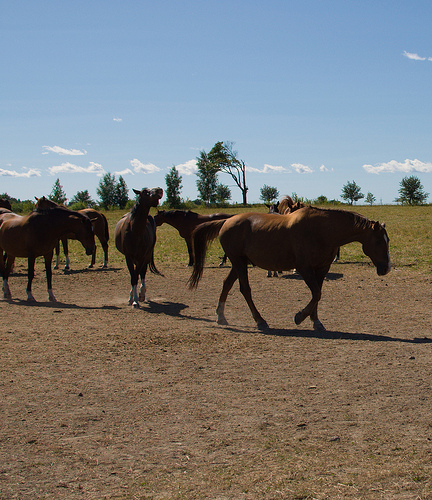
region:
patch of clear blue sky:
[32, 20, 382, 106]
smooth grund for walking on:
[54, 385, 431, 489]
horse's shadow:
[316, 331, 419, 347]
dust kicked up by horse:
[103, 290, 128, 314]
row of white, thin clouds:
[247, 160, 425, 174]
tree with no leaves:
[203, 140, 246, 201]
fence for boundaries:
[371, 198, 393, 209]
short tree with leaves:
[399, 176, 426, 207]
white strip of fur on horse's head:
[379, 231, 392, 248]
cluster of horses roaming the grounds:
[0, 195, 395, 330]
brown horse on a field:
[181, 204, 390, 334]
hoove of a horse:
[310, 317, 322, 328]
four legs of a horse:
[211, 253, 325, 332]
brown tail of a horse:
[183, 217, 228, 292]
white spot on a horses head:
[382, 232, 388, 243]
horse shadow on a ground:
[211, 318, 430, 347]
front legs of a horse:
[293, 259, 331, 332]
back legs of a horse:
[214, 258, 273, 332]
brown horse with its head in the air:
[112, 185, 167, 307]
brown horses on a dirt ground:
[0, 185, 393, 338]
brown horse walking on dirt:
[187, 200, 398, 343]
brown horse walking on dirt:
[1, 192, 103, 325]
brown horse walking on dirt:
[34, 190, 136, 277]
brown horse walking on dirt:
[102, 168, 179, 327]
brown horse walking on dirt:
[157, 192, 235, 274]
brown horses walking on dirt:
[0, 163, 410, 382]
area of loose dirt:
[152, 394, 235, 468]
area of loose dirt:
[19, 334, 78, 395]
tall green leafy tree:
[157, 155, 190, 207]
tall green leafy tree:
[92, 168, 126, 214]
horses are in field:
[22, 192, 364, 359]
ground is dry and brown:
[130, 358, 368, 479]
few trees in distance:
[3, 170, 418, 211]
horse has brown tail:
[156, 213, 272, 267]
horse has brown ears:
[345, 205, 382, 231]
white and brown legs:
[196, 271, 345, 329]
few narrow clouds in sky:
[1, 134, 395, 195]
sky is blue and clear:
[103, 8, 309, 85]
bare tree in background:
[201, 150, 268, 211]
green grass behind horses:
[346, 207, 420, 254]